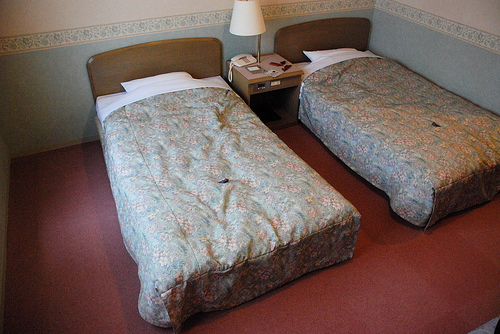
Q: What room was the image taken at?
A: It was taken at the bedroom.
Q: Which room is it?
A: It is a bedroom.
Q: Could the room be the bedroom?
A: Yes, it is the bedroom.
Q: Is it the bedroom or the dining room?
A: It is the bedroom.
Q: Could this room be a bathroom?
A: No, it is a bedroom.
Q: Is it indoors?
A: Yes, it is indoors.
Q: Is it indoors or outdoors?
A: It is indoors.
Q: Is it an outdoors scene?
A: No, it is indoors.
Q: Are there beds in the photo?
A: Yes, there is a bed.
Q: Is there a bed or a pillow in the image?
A: Yes, there is a bed.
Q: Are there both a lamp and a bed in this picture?
A: Yes, there are both a bed and a lamp.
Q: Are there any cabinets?
A: No, there are no cabinets.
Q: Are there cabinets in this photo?
A: No, there are no cabinets.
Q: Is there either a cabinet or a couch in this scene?
A: No, there are no cabinets or couches.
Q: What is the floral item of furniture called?
A: The piece of furniture is a bed.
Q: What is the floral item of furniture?
A: The piece of furniture is a bed.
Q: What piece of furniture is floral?
A: The piece of furniture is a bed.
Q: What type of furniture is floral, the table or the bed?
A: The bed is floral.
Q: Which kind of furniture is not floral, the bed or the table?
A: The table is not floral.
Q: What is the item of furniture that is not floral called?
A: The piece of furniture is a table.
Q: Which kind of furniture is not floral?
A: The furniture is a table.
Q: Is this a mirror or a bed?
A: This is a bed.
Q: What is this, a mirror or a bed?
A: This is a bed.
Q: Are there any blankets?
A: Yes, there is a blanket.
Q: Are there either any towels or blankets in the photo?
A: Yes, there is a blanket.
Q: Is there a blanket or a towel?
A: Yes, there is a blanket.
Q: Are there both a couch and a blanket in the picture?
A: No, there is a blanket but no couches.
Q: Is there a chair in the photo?
A: No, there are no chairs.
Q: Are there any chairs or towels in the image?
A: No, there are no chairs or towels.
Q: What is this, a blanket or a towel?
A: This is a blanket.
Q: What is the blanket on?
A: The blanket is on the bed.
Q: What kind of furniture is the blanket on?
A: The blanket is on the bed.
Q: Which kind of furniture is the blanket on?
A: The blanket is on the bed.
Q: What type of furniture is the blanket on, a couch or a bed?
A: The blanket is on a bed.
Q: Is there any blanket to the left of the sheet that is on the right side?
A: Yes, there is a blanket to the left of the bed sheet.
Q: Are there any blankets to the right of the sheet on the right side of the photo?
A: No, the blanket is to the left of the sheet.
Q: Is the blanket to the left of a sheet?
A: Yes, the blanket is to the left of a sheet.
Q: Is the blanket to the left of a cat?
A: No, the blanket is to the left of a sheet.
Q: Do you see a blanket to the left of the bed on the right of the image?
A: Yes, there is a blanket to the left of the bed.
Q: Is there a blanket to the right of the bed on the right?
A: No, the blanket is to the left of the bed.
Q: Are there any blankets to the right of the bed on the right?
A: No, the blanket is to the left of the bed.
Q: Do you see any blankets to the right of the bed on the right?
A: No, the blanket is to the left of the bed.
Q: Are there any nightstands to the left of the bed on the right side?
A: No, there is a blanket to the left of the bed.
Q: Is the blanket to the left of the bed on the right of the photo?
A: Yes, the blanket is to the left of the bed.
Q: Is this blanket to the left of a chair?
A: No, the blanket is to the left of the bed.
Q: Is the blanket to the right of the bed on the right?
A: No, the blanket is to the left of the bed.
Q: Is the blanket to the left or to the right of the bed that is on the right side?
A: The blanket is to the left of the bed.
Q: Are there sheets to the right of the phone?
A: Yes, there is a sheet to the right of the phone.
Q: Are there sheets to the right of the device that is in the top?
A: Yes, there is a sheet to the right of the phone.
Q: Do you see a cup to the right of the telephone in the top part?
A: No, there is a sheet to the right of the telephone.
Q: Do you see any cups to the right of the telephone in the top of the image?
A: No, there is a sheet to the right of the telephone.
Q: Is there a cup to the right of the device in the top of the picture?
A: No, there is a sheet to the right of the telephone.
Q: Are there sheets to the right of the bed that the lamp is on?
A: Yes, there is a sheet to the right of the bed.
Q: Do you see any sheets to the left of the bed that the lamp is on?
A: No, the sheet is to the right of the bed.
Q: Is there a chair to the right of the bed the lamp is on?
A: No, there is a sheet to the right of the bed.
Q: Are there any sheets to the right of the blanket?
A: Yes, there is a sheet to the right of the blanket.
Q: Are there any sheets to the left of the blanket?
A: No, the sheet is to the right of the blanket.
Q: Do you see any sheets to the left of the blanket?
A: No, the sheet is to the right of the blanket.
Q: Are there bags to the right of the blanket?
A: No, there is a sheet to the right of the blanket.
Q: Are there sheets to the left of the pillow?
A: No, the sheet is to the right of the pillow.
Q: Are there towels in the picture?
A: No, there are no towels.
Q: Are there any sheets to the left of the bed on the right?
A: Yes, there are sheets to the left of the bed.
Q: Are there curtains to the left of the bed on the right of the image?
A: No, there are sheets to the left of the bed.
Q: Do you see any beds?
A: Yes, there is a bed.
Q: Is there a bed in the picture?
A: Yes, there is a bed.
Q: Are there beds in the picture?
A: Yes, there is a bed.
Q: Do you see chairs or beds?
A: Yes, there is a bed.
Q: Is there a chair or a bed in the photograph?
A: Yes, there is a bed.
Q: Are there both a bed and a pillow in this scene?
A: Yes, there are both a bed and a pillow.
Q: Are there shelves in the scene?
A: No, there are no shelves.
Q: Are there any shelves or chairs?
A: No, there are no shelves or chairs.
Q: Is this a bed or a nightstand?
A: This is a bed.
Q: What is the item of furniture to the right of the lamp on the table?
A: The piece of furniture is a bed.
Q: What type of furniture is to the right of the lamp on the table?
A: The piece of furniture is a bed.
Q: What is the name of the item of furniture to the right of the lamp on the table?
A: The piece of furniture is a bed.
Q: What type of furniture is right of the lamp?
A: The piece of furniture is a bed.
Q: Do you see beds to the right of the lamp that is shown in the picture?
A: Yes, there is a bed to the right of the lamp.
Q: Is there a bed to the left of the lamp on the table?
A: No, the bed is to the right of the lamp.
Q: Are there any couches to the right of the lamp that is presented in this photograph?
A: No, there is a bed to the right of the lamp.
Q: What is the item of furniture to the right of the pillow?
A: The piece of furniture is a bed.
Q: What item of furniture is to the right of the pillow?
A: The piece of furniture is a bed.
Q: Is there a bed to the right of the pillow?
A: Yes, there is a bed to the right of the pillow.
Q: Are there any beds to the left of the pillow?
A: No, the bed is to the right of the pillow.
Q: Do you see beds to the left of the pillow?
A: No, the bed is to the right of the pillow.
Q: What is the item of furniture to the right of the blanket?
A: The piece of furniture is a bed.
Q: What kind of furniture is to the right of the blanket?
A: The piece of furniture is a bed.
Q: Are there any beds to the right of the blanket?
A: Yes, there is a bed to the right of the blanket.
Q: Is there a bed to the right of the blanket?
A: Yes, there is a bed to the right of the blanket.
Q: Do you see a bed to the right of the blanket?
A: Yes, there is a bed to the right of the blanket.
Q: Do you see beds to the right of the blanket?
A: Yes, there is a bed to the right of the blanket.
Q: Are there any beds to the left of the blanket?
A: No, the bed is to the right of the blanket.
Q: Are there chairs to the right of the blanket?
A: No, there is a bed to the right of the blanket.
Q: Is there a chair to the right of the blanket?
A: No, there is a bed to the right of the blanket.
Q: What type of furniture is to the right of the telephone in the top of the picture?
A: The piece of furniture is a bed.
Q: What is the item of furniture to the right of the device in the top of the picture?
A: The piece of furniture is a bed.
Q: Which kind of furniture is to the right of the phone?
A: The piece of furniture is a bed.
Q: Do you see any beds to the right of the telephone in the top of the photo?
A: Yes, there is a bed to the right of the phone.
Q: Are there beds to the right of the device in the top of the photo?
A: Yes, there is a bed to the right of the phone.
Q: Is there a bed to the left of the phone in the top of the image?
A: No, the bed is to the right of the phone.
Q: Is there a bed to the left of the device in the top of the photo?
A: No, the bed is to the right of the phone.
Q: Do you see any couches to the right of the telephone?
A: No, there is a bed to the right of the telephone.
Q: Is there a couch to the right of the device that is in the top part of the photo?
A: No, there is a bed to the right of the telephone.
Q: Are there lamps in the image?
A: Yes, there is a lamp.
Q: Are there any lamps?
A: Yes, there is a lamp.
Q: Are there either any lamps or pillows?
A: Yes, there is a lamp.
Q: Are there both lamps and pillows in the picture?
A: Yes, there are both a lamp and a pillow.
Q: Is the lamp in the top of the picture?
A: Yes, the lamp is in the top of the image.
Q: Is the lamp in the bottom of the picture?
A: No, the lamp is in the top of the image.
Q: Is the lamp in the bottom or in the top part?
A: The lamp is in the top of the image.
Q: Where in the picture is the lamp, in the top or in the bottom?
A: The lamp is in the top of the image.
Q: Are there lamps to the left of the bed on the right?
A: Yes, there is a lamp to the left of the bed.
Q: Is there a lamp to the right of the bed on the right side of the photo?
A: No, the lamp is to the left of the bed.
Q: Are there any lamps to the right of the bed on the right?
A: No, the lamp is to the left of the bed.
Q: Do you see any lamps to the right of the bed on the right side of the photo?
A: No, the lamp is to the left of the bed.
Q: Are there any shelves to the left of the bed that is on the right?
A: No, there is a lamp to the left of the bed.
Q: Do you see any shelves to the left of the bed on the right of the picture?
A: No, there is a lamp to the left of the bed.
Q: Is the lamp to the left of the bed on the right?
A: Yes, the lamp is to the left of the bed.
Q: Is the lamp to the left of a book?
A: No, the lamp is to the left of the bed.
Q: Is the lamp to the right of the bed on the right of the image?
A: No, the lamp is to the left of the bed.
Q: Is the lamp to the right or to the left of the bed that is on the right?
A: The lamp is to the left of the bed.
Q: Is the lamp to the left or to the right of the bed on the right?
A: The lamp is to the left of the bed.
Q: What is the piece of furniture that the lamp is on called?
A: The piece of furniture is a bed.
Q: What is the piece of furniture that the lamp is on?
A: The piece of furniture is a bed.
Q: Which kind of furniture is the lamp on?
A: The lamp is on the bed.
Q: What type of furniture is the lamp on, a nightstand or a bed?
A: The lamp is on a bed.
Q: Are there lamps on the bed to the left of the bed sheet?
A: Yes, there is a lamp on the bed.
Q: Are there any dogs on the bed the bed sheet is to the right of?
A: No, there is a lamp on the bed.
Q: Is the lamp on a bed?
A: Yes, the lamp is on a bed.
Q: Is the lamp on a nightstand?
A: No, the lamp is on a bed.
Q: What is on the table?
A: The lamp is on the table.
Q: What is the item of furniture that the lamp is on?
A: The piece of furniture is a table.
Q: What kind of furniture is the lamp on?
A: The lamp is on the table.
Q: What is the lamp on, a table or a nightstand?
A: The lamp is on a table.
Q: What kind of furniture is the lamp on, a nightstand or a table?
A: The lamp is on a table.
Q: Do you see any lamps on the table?
A: Yes, there is a lamp on the table.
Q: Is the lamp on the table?
A: Yes, the lamp is on the table.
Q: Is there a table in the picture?
A: Yes, there is a table.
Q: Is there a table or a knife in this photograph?
A: Yes, there is a table.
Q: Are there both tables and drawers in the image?
A: No, there is a table but no drawers.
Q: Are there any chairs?
A: No, there are no chairs.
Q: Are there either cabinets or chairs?
A: No, there are no chairs or cabinets.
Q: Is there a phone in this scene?
A: Yes, there is a phone.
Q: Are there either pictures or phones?
A: Yes, there is a phone.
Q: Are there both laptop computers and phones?
A: No, there is a phone but no laptops.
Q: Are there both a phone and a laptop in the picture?
A: No, there is a phone but no laptops.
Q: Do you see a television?
A: No, there are no televisions.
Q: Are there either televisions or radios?
A: No, there are no televisions or radios.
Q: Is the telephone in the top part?
A: Yes, the telephone is in the top of the image.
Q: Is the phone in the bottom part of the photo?
A: No, the phone is in the top of the image.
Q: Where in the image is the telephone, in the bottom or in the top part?
A: The telephone is in the top of the image.